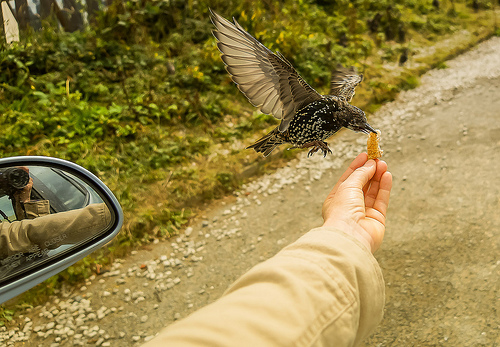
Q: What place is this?
A: It is a road.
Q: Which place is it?
A: It is a road.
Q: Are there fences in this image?
A: No, there are no fences.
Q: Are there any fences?
A: No, there are no fences.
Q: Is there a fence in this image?
A: No, there are no fences.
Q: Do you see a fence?
A: No, there are no fences.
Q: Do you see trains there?
A: No, there are no trains.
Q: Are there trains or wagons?
A: No, there are no trains or wagons.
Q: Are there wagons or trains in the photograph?
A: No, there are no trains or wagons.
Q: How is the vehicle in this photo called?
A: The vehicle is a car.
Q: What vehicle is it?
A: The vehicle is a car.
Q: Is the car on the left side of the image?
A: Yes, the car is on the left of the image.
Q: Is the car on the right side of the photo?
A: No, the car is on the left of the image.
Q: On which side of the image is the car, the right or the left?
A: The car is on the left of the image.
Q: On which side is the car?
A: The car is on the left of the image.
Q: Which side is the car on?
A: The car is on the left of the image.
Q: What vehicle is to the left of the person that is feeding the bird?
A: The vehicle is a car.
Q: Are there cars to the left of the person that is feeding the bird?
A: Yes, there is a car to the left of the person.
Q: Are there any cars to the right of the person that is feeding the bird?
A: No, the car is to the left of the person.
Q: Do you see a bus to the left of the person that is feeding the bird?
A: No, there is a car to the left of the person.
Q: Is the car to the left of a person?
A: Yes, the car is to the left of a person.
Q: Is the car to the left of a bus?
A: No, the car is to the left of a person.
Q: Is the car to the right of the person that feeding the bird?
A: No, the car is to the left of the person.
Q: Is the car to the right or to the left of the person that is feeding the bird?
A: The car is to the left of the person.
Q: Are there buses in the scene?
A: No, there are no buses.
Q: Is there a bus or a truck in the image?
A: No, there are no buses or trucks.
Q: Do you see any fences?
A: No, there are no fences.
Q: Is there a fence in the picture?
A: No, there are no fences.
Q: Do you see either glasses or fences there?
A: No, there are no fences or glasses.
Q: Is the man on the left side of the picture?
A: Yes, the man is on the left of the image.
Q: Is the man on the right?
A: No, the man is on the left of the image.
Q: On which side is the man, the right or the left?
A: The man is on the left of the image.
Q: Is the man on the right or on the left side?
A: The man is on the left of the image.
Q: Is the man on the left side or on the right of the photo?
A: The man is on the left of the image.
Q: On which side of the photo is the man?
A: The man is on the left of the image.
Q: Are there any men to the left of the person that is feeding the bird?
A: Yes, there is a man to the left of the person.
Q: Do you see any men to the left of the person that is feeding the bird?
A: Yes, there is a man to the left of the person.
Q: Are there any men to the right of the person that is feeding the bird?
A: No, the man is to the left of the person.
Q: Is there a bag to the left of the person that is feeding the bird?
A: No, there is a man to the left of the person.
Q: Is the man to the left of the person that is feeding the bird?
A: Yes, the man is to the left of the person.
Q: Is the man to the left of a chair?
A: No, the man is to the left of the person.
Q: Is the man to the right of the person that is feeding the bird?
A: No, the man is to the left of the person.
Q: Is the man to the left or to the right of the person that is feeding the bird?
A: The man is to the left of the person.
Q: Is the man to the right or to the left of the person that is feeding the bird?
A: The man is to the left of the person.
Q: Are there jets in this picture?
A: No, there are no jets.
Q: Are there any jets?
A: No, there are no jets.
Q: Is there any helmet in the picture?
A: No, there are no helmets.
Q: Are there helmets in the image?
A: No, there are no helmets.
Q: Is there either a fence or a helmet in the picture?
A: No, there are no helmets or fences.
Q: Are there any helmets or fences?
A: No, there are no helmets or fences.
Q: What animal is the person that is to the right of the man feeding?
A: The person is feeding the bird.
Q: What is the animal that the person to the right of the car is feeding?
A: The animal is a bird.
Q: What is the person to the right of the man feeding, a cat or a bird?
A: The person is feeding a bird.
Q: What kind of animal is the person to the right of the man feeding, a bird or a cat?
A: The person is feeding a bird.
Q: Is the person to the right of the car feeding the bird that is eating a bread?
A: Yes, the person is feeding the bird.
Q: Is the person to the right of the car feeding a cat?
A: No, the person is feeding the bird.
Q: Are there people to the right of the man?
A: Yes, there is a person to the right of the man.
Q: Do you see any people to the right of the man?
A: Yes, there is a person to the right of the man.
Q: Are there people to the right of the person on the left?
A: Yes, there is a person to the right of the man.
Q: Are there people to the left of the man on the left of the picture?
A: No, the person is to the right of the man.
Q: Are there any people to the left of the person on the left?
A: No, the person is to the right of the man.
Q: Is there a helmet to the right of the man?
A: No, there is a person to the right of the man.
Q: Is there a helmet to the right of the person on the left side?
A: No, there is a person to the right of the man.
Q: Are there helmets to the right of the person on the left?
A: No, there is a person to the right of the man.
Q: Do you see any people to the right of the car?
A: Yes, there is a person to the right of the car.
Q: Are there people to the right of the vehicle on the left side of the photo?
A: Yes, there is a person to the right of the car.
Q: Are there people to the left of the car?
A: No, the person is to the right of the car.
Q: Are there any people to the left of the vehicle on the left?
A: No, the person is to the right of the car.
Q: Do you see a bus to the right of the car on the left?
A: No, there is a person to the right of the car.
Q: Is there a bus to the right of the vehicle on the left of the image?
A: No, there is a person to the right of the car.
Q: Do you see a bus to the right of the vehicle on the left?
A: No, there is a person to the right of the car.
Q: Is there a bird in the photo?
A: Yes, there is a bird.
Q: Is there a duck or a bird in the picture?
A: Yes, there is a bird.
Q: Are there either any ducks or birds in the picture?
A: Yes, there is a bird.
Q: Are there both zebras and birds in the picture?
A: No, there is a bird but no zebras.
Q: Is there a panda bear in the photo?
A: No, there are no pandas.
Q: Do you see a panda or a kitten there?
A: No, there are no pandas or kittens.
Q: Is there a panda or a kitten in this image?
A: No, there are no pandas or kittens.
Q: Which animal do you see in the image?
A: The animal is a bird.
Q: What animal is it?
A: The animal is a bird.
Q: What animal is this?
A: This is a bird.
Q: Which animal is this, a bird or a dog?
A: This is a bird.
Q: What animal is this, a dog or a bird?
A: This is a bird.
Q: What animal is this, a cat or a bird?
A: This is a bird.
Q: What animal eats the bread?
A: The animal is a bird.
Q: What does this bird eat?
A: The bird eats a bread.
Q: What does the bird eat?
A: The bird eats a bread.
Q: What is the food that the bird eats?
A: The food is a bread.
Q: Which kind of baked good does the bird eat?
A: The bird eats a bread.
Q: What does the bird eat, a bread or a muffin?
A: The bird eats a bread.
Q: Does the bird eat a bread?
A: Yes, the bird eats a bread.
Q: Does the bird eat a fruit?
A: No, the bird eats a bread.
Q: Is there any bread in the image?
A: Yes, there is a bread.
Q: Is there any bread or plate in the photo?
A: Yes, there is a bread.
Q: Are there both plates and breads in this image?
A: No, there is a bread but no plates.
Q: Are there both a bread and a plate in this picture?
A: No, there is a bread but no plates.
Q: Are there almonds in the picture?
A: No, there are no almonds.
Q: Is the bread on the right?
A: Yes, the bread is on the right of the image.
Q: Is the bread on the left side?
A: No, the bread is on the right of the image.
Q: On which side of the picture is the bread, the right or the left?
A: The bread is on the right of the image.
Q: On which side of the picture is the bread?
A: The bread is on the right of the image.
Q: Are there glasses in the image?
A: No, there are no glasses.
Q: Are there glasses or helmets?
A: No, there are no glasses or helmets.